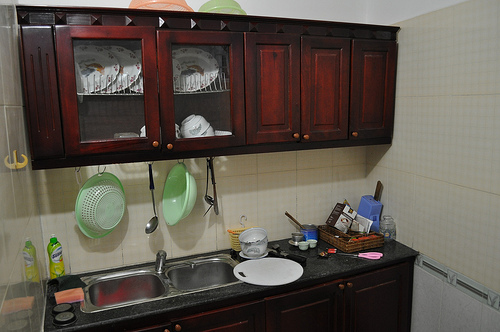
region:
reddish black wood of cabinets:
[18, 22, 408, 158]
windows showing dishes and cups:
[65, 17, 240, 159]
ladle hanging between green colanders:
[55, 160, 203, 236]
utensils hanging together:
[195, 151, 236, 233]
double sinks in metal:
[70, 241, 255, 311]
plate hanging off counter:
[226, 241, 306, 291]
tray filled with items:
[311, 181, 391, 271]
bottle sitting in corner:
[35, 215, 75, 285]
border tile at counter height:
[400, 230, 495, 310]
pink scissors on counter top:
[318, 240, 390, 276]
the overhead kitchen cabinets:
[15, 3, 398, 169]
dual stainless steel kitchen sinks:
[79, 250, 239, 312]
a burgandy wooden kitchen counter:
[42, 225, 417, 330]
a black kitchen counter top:
[45, 225, 417, 325]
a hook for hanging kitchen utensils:
[93, 163, 108, 175]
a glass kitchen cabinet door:
[52, 24, 159, 158]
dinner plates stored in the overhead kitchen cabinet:
[72, 37, 143, 93]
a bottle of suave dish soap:
[45, 231, 65, 277]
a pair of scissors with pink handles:
[332, 249, 382, 259]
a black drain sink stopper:
[50, 309, 74, 324]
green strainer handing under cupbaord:
[73, 170, 128, 240]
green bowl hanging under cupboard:
[159, 162, 198, 225]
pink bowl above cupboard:
[129, 0, 196, 12]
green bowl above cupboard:
[198, 0, 249, 14]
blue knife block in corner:
[357, 190, 384, 233]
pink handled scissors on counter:
[337, 249, 385, 261]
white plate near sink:
[232, 254, 307, 288]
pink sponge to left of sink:
[53, 287, 86, 304]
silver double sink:
[76, 249, 248, 316]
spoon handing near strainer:
[141, 164, 160, 234]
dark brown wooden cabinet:
[18, 4, 413, 171]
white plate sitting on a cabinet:
[225, 254, 307, 292]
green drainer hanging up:
[68, 173, 143, 248]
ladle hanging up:
[136, 158, 167, 243]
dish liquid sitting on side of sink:
[41, 230, 85, 285]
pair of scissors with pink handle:
[331, 247, 387, 267]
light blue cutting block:
[357, 172, 386, 235]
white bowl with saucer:
[233, 227, 280, 257]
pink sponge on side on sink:
[48, 284, 96, 309]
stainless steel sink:
[83, 251, 265, 316]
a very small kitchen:
[18, 56, 477, 313]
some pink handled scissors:
[331, 242, 395, 264]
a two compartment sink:
[71, 240, 254, 319]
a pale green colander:
[72, 167, 145, 242]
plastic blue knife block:
[353, 191, 395, 233]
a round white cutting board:
[227, 249, 307, 294]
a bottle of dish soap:
[36, 225, 72, 282]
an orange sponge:
[50, 282, 95, 301]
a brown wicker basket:
[315, 212, 387, 262]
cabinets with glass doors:
[53, 17, 261, 172]